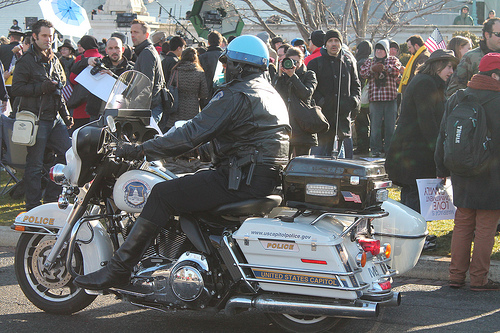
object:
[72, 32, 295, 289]
cop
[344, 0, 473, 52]
tree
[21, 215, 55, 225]
word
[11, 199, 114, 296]
fender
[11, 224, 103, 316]
black tire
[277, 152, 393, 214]
box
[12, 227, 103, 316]
tire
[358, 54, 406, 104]
coat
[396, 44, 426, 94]
scarf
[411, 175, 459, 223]
sign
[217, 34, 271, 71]
blue helmet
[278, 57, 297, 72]
holding camera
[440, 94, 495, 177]
backpack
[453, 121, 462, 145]
white logo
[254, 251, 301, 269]
white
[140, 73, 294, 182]
coat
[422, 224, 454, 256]
grass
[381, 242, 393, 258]
tail lights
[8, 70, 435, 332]
motorcycle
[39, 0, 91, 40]
umbrella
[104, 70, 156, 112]
windscreen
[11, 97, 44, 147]
shoulder bag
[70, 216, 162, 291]
boot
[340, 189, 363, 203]
flag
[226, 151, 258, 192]
holster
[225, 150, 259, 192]
gun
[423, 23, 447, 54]
flag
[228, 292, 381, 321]
exhaust pipe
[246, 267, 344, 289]
united states-capitol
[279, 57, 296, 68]
camera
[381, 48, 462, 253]
person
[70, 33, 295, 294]
man